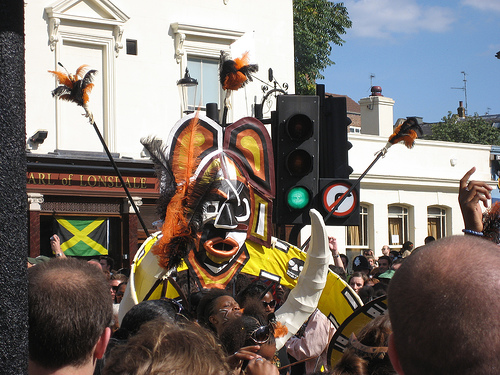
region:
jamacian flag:
[51, 207, 118, 259]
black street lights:
[260, 91, 352, 241]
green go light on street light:
[265, 169, 318, 225]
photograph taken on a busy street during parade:
[21, 28, 465, 367]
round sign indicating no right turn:
[313, 175, 371, 230]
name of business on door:
[26, 162, 158, 205]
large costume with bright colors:
[120, 114, 308, 306]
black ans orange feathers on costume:
[37, 55, 105, 121]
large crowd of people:
[32, 212, 486, 361]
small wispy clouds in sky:
[320, 4, 490, 54]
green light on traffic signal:
[285, 181, 310, 215]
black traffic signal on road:
[280, 93, 317, 217]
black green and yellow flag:
[53, 209, 116, 260]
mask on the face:
[199, 156, 253, 277]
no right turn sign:
[328, 178, 355, 223]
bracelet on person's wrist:
[460, 223, 487, 240]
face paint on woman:
[215, 309, 233, 324]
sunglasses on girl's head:
[253, 311, 280, 347]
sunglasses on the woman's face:
[263, 298, 278, 310]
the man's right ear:
[91, 323, 109, 361]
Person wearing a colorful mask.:
[142, 114, 277, 272]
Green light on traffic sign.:
[274, 183, 316, 218]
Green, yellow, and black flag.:
[55, 210, 112, 263]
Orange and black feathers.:
[47, 59, 98, 112]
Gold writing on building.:
[22, 172, 151, 189]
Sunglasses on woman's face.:
[261, 296, 276, 311]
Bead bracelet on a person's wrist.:
[463, 227, 484, 238]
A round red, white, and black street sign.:
[319, 183, 357, 220]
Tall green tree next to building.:
[292, 0, 351, 94]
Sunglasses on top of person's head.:
[239, 320, 276, 351]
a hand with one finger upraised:
[457, 164, 496, 237]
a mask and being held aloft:
[45, 52, 423, 339]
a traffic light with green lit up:
[265, 83, 323, 229]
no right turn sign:
[320, 176, 361, 226]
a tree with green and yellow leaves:
[291, 0, 354, 94]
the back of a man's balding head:
[24, 253, 114, 374]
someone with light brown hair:
[100, 310, 235, 373]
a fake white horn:
[267, 206, 330, 351]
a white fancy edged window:
[169, 20, 246, 131]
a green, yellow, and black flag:
[55, 216, 110, 259]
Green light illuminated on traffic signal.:
[290, 184, 325, 226]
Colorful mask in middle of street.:
[191, 155, 249, 266]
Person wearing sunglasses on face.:
[255, 298, 287, 312]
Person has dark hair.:
[35, 279, 92, 341]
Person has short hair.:
[38, 281, 98, 329]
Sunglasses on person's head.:
[253, 317, 290, 354]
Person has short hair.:
[418, 248, 456, 295]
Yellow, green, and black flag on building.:
[53, 205, 116, 248]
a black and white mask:
[173, 151, 258, 269]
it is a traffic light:
[273, 95, 322, 227]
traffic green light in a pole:
[277, 86, 319, 213]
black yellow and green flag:
[51, 218, 111, 257]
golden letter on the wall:
[26, 168, 155, 194]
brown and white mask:
[174, 148, 249, 254]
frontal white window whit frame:
[176, 25, 220, 88]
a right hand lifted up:
[456, 170, 488, 226]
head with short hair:
[403, 244, 488, 351]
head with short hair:
[35, 265, 102, 342]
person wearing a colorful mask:
[168, 107, 283, 297]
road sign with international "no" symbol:
[322, 175, 366, 226]